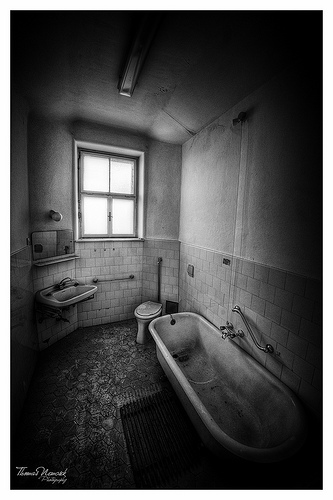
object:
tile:
[64, 387, 79, 400]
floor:
[10, 318, 320, 500]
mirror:
[31, 229, 74, 260]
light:
[47, 209, 62, 223]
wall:
[27, 119, 179, 347]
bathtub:
[149, 312, 299, 454]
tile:
[272, 285, 295, 315]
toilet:
[134, 299, 163, 343]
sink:
[38, 279, 98, 309]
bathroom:
[10, 11, 322, 489]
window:
[73, 140, 143, 240]